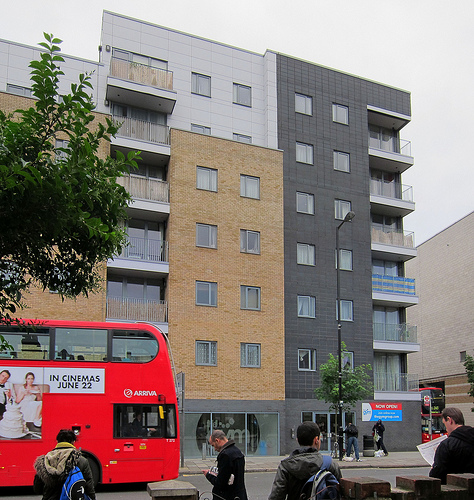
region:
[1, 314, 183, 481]
red double decker bus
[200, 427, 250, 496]
man holding newspaper under arm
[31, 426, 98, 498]
young man with backpack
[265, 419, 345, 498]
young man with blue backpack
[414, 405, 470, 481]
man reading newspaper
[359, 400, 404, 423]
red, white, blue sign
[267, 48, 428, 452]
gray apartment on corner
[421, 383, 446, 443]
red double decker bus around corner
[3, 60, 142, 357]
green tree beside bus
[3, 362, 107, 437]
sign on red bus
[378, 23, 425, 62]
A clear overcast sky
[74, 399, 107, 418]
Small part of the red bus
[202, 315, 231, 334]
Tan part of the building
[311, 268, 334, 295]
Black part of the building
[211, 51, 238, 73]
Gray part of the building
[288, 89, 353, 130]
Top two windows in the black part of the building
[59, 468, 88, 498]
Blue and black backpack of pedestrian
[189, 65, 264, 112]
Top two windows in the gray part of the building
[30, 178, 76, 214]
Green leaves on the tree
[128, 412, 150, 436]
Bus driver in the red bus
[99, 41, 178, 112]
Apartment balcony with railings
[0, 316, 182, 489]
Red double decker bus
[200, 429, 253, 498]
Man in black looking down at something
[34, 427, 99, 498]
Person wearing hooded jacked with blue back pack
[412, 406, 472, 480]
Man in black reading the paper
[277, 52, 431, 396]
Grey tiled apartment complex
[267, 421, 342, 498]
Man in dark jacket with back pack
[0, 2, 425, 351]
Multi floored apartment complex building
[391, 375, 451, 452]
Red bus behind building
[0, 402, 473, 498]
Pedestrians beside road way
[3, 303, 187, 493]
the bus is red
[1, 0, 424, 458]
the building is 7 stories tall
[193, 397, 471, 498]
the men are wearing black jackets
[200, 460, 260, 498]
the man has something under his arm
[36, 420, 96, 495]
the person has a blue backpack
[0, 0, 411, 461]
the building is brown white and black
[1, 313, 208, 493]
the bus has 2 levels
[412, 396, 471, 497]
the man is reading something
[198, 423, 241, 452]
the man is balding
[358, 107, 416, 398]
the rooms have balconies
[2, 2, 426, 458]
a 7 story building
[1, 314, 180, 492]
a red double decker bus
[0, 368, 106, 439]
a movie ad on the side of the bus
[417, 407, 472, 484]
a man wearing a black jacket reading a newspaper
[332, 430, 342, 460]
a bicycle on the other side of the street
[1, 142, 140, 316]
a leafy green tree on the side of the picture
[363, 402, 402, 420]
a sign on the building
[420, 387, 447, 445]
a red double decker bus on the street next to the building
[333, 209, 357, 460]
a tall street light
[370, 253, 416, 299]
a balcony with a blue and white covered railing